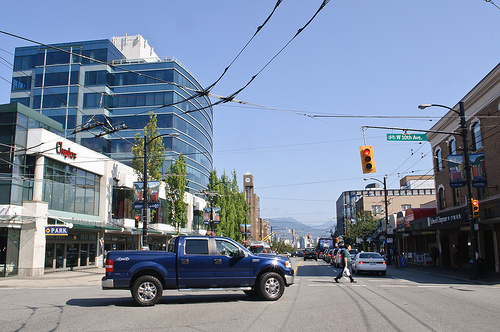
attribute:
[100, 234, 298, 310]
truck — blue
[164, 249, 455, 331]
street — gray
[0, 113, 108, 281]
building — white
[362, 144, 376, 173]
stoplight — red, yellow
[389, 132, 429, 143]
street sign — green, white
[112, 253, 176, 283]
back of truck — blue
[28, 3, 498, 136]
sky — blue